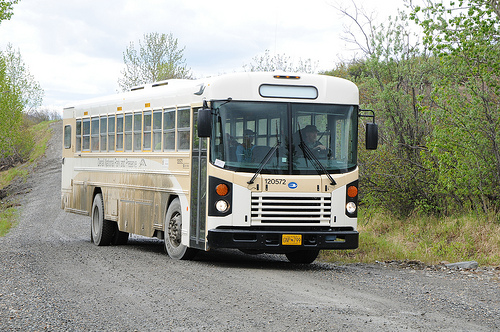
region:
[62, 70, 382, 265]
white bus on gravel road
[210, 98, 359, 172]
front windshield on bus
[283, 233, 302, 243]
yellow license plate on bus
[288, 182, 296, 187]
logo on front of bus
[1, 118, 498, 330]
gravel road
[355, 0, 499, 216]
trees growing on side of road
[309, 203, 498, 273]
grass on side of road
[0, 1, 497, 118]
sky full of white clouds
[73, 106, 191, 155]
passenger windows on bus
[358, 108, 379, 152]
driver side mirror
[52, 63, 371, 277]
white bus on dirt road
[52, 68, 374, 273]
bus covered with mud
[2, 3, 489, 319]
road in middle of vegetation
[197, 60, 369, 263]
bus with yellow licence plate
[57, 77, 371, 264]
man driving white bus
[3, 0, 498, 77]
sky is partly cloudy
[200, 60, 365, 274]
bus with red and white headlights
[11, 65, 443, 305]
bus on dark gray road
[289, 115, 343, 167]
bus driver wearing dark har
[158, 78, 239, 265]
door of bus is closed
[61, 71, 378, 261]
A white bus with a driver in a hat.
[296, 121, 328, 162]
A driver of the white bus wearing a hat.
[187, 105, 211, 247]
Black double doors of a bus.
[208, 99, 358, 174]
Very large two pane window of a bus.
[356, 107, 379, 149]
Black rear view mirror by a driver of the bus.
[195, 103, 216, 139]
Back of a black mirror on the side of the bus with the doors.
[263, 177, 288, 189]
The number 120572 on the front of a white bus.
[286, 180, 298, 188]
A blue oval with white mark inside it.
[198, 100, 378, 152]
Two black rear view mirrors on the front of a bus.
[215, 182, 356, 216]
All the white and orange headlights on the front of the bus.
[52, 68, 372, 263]
white bus driving down road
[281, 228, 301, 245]
yellow front license plate of bus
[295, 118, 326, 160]
driver sitting in bus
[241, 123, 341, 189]
two windshield wipers of bus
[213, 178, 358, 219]
front lights of bus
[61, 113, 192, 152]
windows on side of bus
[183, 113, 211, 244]
doors of the white bus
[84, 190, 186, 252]
wheels of the bus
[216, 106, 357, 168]
windshield of the white bus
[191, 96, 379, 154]
black side mirros of bus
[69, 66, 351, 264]
white bus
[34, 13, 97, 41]
white clouds in blue sky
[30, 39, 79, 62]
white clouds in blue sky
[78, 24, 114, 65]
white clouds in blue sky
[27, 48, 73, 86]
white clouds in blue sky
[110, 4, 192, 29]
white clouds in blue sky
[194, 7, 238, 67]
white clouds in blue sky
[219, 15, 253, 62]
white clouds in blue sky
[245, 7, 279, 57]
white clouds in blue sky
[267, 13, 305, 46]
white clouds in blue sky